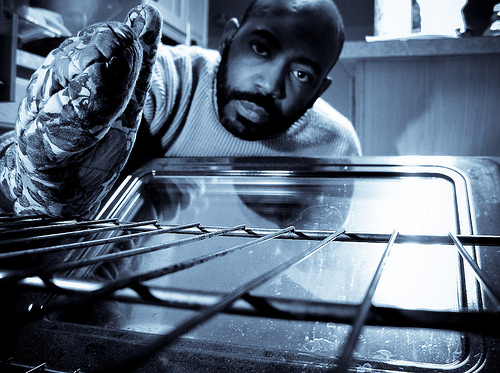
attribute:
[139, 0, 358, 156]
man — looking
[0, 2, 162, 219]
oven mitt — patterned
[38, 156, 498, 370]
oven door — glass, open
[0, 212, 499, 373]
oven rack — black, inside, metal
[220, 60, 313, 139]
beard — black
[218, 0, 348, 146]
face — bald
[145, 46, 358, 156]
sweater — ribbed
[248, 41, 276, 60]
eye — dark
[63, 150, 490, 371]
window — glass